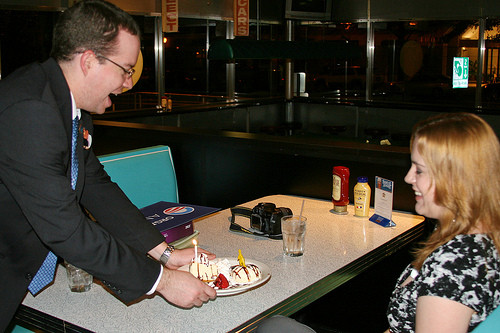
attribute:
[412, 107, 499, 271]
hair — strawberry blonde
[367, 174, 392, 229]
menu — plastic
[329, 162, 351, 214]
ketchup bottle — red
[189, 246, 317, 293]
cakes — white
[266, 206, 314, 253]
glass — water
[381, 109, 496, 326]
woman — smiling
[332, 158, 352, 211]
bottle — red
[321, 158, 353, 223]
ketchup bottle — red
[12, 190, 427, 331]
table — upside down, speckled, formica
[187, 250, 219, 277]
cake — white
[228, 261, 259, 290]
cake — white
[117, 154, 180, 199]
vinyl seat — baby blue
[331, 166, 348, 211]
bottle — red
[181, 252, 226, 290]
cake — white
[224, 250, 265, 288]
cake — white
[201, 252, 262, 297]
cakes — white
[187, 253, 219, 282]
cake — white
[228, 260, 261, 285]
cake — white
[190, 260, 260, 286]
cakes — white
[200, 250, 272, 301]
cakes — white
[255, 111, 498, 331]
woman — smiling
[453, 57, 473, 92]
sign — white, green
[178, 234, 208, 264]
candle — white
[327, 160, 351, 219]
ketchup — Red 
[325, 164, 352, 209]
ketchup — red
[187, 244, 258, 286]
cake — white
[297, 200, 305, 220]
straw — plastic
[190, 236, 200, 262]
candle — lit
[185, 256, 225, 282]
cake — birthday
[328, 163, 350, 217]
ketchup — bottle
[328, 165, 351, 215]
bottle — red, ketchup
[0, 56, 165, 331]
suit — grey, black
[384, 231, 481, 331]
top — black, white